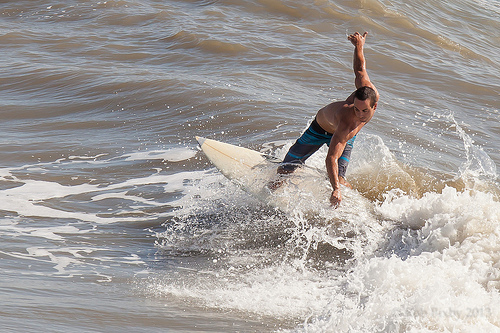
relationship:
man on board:
[263, 30, 381, 215] [193, 136, 373, 235]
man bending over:
[263, 30, 381, 215] [303, 130, 357, 194]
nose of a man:
[356, 111, 364, 119] [263, 30, 381, 215]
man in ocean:
[263, 30, 381, 215] [2, 2, 498, 330]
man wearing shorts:
[263, 30, 381, 215] [277, 117, 359, 178]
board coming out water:
[193, 136, 373, 235] [2, 2, 498, 330]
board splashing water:
[193, 136, 373, 235] [2, 2, 498, 330]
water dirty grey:
[2, 2, 498, 330] [51, 34, 183, 109]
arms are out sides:
[327, 117, 352, 207] [264, 99, 344, 156]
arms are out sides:
[347, 28, 384, 94] [264, 99, 344, 156]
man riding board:
[263, 30, 381, 215] [193, 136, 373, 235]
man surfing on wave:
[263, 30, 381, 215] [244, 116, 496, 331]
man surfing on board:
[263, 30, 381, 215] [193, 124, 328, 228]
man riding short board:
[263, 30, 381, 215] [193, 124, 328, 228]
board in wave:
[193, 124, 328, 228] [244, 116, 496, 331]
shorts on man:
[277, 117, 359, 178] [263, 30, 381, 215]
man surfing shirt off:
[263, 30, 381, 215] [318, 96, 371, 139]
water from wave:
[2, 2, 498, 330] [244, 116, 496, 331]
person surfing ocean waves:
[263, 30, 381, 215] [164, 57, 485, 328]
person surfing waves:
[263, 30, 381, 215] [164, 57, 485, 328]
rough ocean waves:
[379, 183, 498, 325] [164, 57, 485, 328]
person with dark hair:
[263, 30, 381, 215] [351, 85, 378, 108]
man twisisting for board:
[263, 30, 381, 215] [193, 136, 373, 235]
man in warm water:
[194, 32, 379, 223] [2, 2, 498, 330]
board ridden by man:
[193, 136, 373, 235] [263, 30, 381, 215]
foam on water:
[6, 154, 210, 280] [2, 2, 498, 330]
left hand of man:
[346, 29, 372, 46] [194, 32, 379, 223]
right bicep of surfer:
[334, 130, 350, 157] [263, 30, 381, 215]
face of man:
[351, 98, 373, 124] [194, 32, 379, 223]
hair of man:
[351, 85, 378, 108] [194, 32, 379, 223]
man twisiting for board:
[194, 32, 379, 223] [193, 136, 373, 235]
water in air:
[2, 2, 498, 330] [390, 102, 486, 179]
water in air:
[2, 2, 498, 330] [156, 176, 346, 285]